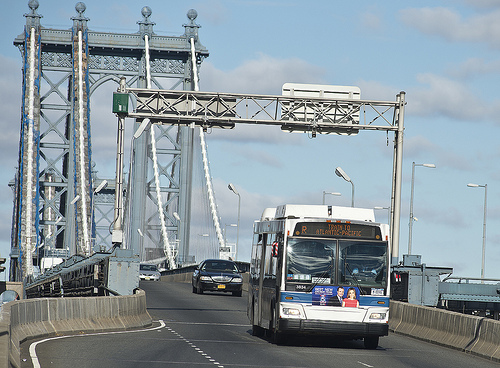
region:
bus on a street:
[240, 199, 398, 355]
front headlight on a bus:
[280, 304, 303, 321]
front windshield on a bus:
[282, 230, 393, 298]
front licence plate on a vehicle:
[213, 280, 228, 292]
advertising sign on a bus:
[308, 282, 363, 311]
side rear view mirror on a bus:
[268, 228, 285, 268]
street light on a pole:
[461, 177, 493, 202]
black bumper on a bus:
[276, 314, 391, 342]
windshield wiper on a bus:
[339, 247, 369, 299]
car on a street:
[188, 255, 248, 302]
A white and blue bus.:
[248, 203, 393, 351]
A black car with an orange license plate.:
[191, 258, 241, 294]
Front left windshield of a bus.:
[287, 235, 337, 285]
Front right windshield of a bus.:
[339, 243, 386, 296]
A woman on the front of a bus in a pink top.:
[343, 288, 360, 310]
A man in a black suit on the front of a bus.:
[324, 287, 344, 306]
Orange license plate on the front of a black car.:
[216, 282, 226, 289]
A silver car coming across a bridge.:
[137, 262, 160, 284]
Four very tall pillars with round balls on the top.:
[8, 2, 209, 282]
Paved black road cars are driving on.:
[30, 279, 485, 366]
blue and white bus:
[252, 199, 390, 338]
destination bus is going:
[292, 217, 392, 248]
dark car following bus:
[193, 262, 246, 316]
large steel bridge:
[21, 12, 211, 277]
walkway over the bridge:
[438, 274, 497, 304]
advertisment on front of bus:
[316, 283, 382, 308]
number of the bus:
[285, 273, 318, 305]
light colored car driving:
[142, 260, 173, 291]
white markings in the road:
[168, 328, 218, 367]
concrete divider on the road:
[4, 296, 150, 337]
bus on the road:
[233, 205, 416, 349]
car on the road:
[180, 249, 246, 299]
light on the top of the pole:
[401, 154, 441, 260]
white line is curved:
[19, 307, 169, 366]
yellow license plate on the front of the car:
[213, 278, 228, 293]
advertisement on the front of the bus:
[308, 285, 365, 307]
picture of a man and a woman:
[333, 286, 360, 307]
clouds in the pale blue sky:
[1, 2, 497, 263]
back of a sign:
[277, 81, 362, 134]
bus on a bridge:
[217, 191, 422, 353]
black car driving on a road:
[180, 249, 246, 307]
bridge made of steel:
[8, 17, 242, 277]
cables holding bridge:
[10, 99, 115, 254]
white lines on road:
[162, 317, 211, 366]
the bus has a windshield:
[273, 209, 395, 322]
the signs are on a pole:
[119, 64, 412, 315]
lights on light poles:
[408, 152, 498, 258]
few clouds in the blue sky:
[294, 12, 474, 172]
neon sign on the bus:
[289, 221, 393, 271]